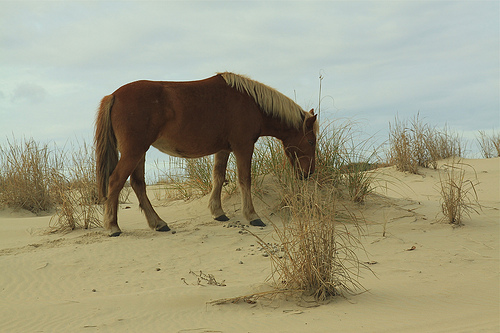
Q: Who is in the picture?
A: A horse.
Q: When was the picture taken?
A: At daytime.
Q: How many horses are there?
A: One.